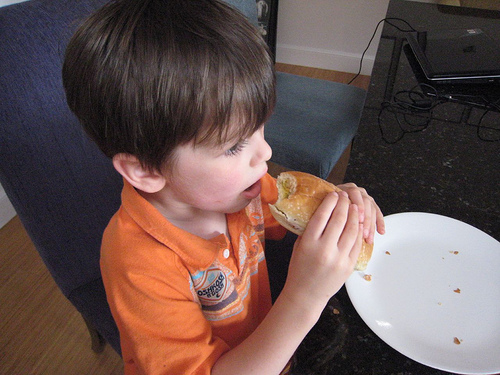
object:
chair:
[0, 0, 120, 355]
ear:
[110, 150, 166, 195]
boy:
[61, 0, 385, 375]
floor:
[0, 62, 369, 375]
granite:
[288, 0, 499, 375]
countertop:
[283, 0, 499, 375]